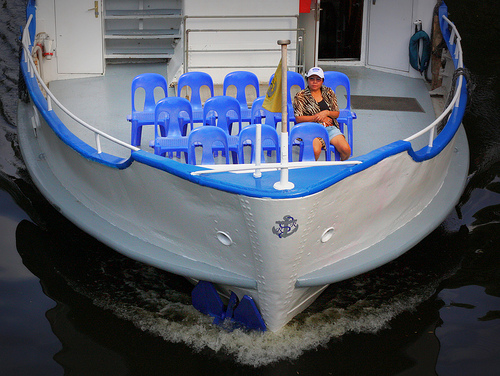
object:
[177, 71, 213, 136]
chair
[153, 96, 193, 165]
chair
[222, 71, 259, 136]
chair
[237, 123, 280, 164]
chair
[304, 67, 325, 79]
hat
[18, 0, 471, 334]
boat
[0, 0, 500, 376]
river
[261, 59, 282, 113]
flag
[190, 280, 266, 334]
anchor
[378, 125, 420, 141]
ground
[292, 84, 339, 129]
shirt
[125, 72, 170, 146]
blue chair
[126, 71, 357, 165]
chairs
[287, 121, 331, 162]
blue chair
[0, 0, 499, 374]
water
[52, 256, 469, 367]
ripples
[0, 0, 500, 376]
wave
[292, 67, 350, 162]
woman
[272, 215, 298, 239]
logo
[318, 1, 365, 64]
door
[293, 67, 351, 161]
person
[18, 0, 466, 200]
rim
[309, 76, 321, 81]
sunglasses